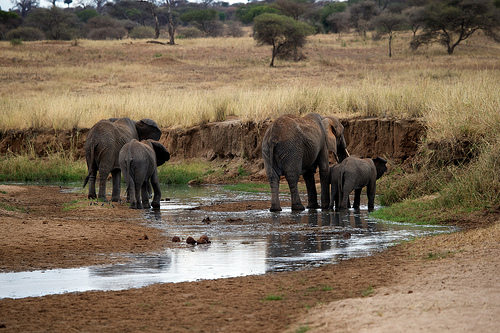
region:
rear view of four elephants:
[76, 97, 398, 222]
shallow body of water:
[115, 200, 450, 304]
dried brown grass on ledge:
[185, 72, 280, 131]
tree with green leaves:
[247, 10, 314, 76]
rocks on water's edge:
[167, 230, 217, 250]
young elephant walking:
[318, 146, 395, 206]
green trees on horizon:
[58, 7, 231, 45]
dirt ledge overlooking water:
[192, 118, 256, 163]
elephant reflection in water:
[250, 234, 299, 273]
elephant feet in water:
[260, 197, 312, 220]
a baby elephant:
[326, 147, 391, 212]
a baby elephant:
[122, 138, 173, 222]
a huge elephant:
[258, 101, 340, 226]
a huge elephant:
[79, 111, 157, 202]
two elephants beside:
[80, 102, 175, 218]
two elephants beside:
[260, 100, 396, 206]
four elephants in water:
[78, 90, 398, 237]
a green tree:
[245, 12, 304, 77]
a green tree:
[416, 5, 495, 59]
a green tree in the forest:
[181, 2, 226, 38]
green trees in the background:
[251, 15, 292, 57]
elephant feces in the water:
[176, 232, 223, 252]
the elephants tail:
[263, 144, 279, 182]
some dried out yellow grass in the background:
[78, 55, 153, 98]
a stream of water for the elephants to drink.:
[86, 262, 116, 282]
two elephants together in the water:
[268, 115, 383, 212]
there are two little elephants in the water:
[80, 120, 175, 198]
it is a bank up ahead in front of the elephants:
[198, 126, 243, 157]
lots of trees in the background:
[382, 18, 463, 50]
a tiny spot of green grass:
[264, 285, 286, 312]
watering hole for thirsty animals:
[6, 223, 399, 310]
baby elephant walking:
[330, 152, 386, 207]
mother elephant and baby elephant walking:
[260, 110, 390, 217]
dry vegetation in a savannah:
[371, 75, 494, 130]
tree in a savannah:
[250, 12, 310, 67]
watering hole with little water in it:
[1, 195, 451, 318]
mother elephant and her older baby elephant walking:
[76, 112, 171, 212]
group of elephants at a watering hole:
[71, 110, 391, 227]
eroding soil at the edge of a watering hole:
[187, 120, 260, 175]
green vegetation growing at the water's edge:
[164, 163, 254, 198]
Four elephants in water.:
[61, 100, 461, 255]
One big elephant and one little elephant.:
[255, 80, 390, 220]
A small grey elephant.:
[320, 145, 390, 220]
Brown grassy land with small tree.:
[170, 0, 325, 115]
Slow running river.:
[35, 215, 320, 330]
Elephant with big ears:
[115, 135, 175, 215]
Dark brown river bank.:
[30, 230, 445, 324]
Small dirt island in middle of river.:
[190, 190, 295, 240]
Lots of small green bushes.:
[0, 0, 210, 60]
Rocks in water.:
[95, 210, 470, 305]